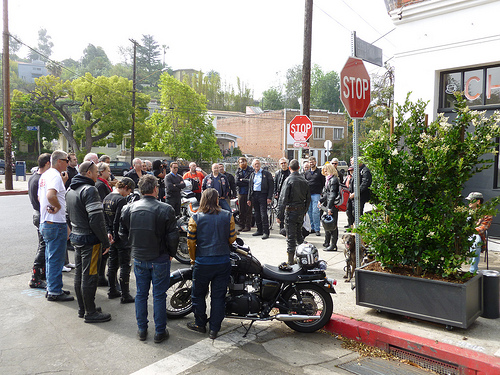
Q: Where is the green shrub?
A: Behind the bike.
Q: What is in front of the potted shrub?
A: A stop sign.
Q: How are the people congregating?
A: In a circle.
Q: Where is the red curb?
A: Next to the bike.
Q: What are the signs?
A: Stop signs.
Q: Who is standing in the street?
A: Bikers.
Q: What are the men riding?
A: Motorcycles.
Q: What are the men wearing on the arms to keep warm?
A: Jackets.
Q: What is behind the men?
A: Trees.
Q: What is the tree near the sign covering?
A: A building.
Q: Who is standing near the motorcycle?
A: A woman.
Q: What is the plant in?
A: A box.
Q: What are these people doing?
A: Listening to a speech.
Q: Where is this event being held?
A: Downtown.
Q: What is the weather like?
A: Sunny.